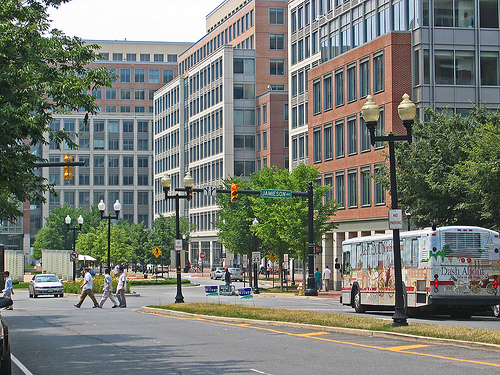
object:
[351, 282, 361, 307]
tire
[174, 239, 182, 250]
sign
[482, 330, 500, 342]
grass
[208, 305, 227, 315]
signs grass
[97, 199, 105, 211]
light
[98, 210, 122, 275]
pole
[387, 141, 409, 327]
lampposts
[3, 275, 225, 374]
road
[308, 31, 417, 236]
panel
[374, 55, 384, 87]
window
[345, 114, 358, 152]
window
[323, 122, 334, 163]
window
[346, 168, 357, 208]
window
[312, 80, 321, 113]
window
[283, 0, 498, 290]
building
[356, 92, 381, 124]
light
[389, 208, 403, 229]
sign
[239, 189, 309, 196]
post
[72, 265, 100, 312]
man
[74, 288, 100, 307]
pants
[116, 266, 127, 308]
people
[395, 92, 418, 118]
light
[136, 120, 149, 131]
windows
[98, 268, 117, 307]
person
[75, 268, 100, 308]
person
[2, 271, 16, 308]
person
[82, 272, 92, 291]
shirt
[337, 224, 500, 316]
bus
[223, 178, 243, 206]
light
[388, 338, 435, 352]
stripes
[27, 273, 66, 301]
car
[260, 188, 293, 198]
street sign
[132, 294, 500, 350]
island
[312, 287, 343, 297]
sidewalk